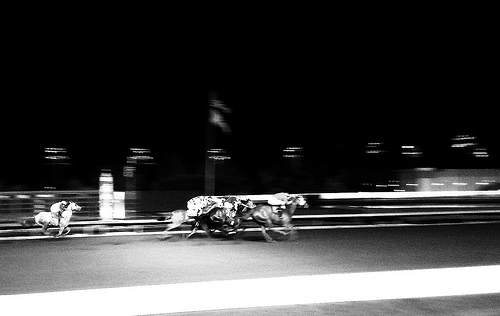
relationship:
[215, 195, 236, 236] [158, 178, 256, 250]
man on horse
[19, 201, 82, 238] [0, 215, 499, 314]
horse racing down track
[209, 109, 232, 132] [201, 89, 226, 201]
flag flying on a pole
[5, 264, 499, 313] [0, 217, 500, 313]
light shining on ground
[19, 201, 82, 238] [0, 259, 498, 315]
horse running by fence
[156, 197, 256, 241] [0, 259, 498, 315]
horse running by fence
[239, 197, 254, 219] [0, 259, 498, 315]
horse running by fence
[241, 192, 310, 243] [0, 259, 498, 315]
horse running by fence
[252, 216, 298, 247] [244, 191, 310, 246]
legs on horse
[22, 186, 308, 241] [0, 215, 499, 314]
horses racing down track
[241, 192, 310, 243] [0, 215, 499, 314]
horse racing down track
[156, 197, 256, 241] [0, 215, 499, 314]
horse racing down track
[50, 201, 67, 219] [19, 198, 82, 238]
man on horse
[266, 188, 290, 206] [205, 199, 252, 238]
jockey on horse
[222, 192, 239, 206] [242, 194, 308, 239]
jockey on horse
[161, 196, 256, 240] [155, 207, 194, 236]
jockey on horse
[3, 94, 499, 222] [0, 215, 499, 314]
lights lining track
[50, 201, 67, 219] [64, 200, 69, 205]
man wearing hat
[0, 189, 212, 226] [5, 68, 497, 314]
fence on side of race track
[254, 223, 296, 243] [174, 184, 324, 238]
legs of horse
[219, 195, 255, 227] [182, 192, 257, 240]
man on horse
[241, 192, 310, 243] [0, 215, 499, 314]
horse racing on track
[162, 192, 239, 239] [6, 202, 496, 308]
horse on track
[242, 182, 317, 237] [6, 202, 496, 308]
horse on track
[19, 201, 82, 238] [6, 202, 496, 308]
horse on track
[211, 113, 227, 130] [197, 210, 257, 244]
flag behind horse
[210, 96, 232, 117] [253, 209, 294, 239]
flag behind horse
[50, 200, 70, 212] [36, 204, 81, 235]
jokcey on horse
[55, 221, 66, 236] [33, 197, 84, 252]
legs of horse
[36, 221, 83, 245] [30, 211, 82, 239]
legs of horse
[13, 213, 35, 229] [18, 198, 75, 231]
tail of horse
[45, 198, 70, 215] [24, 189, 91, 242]
man riding horse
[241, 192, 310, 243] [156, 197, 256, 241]
horse behind horse